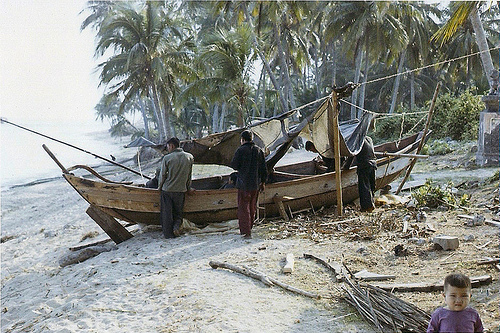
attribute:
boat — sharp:
[46, 122, 497, 224]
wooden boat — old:
[18, 105, 429, 229]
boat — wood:
[47, 77, 447, 244]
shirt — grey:
[149, 146, 196, 195]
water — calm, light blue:
[23, 122, 110, 167]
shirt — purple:
[432, 308, 477, 331]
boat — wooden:
[33, 136, 480, 236]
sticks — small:
[332, 275, 437, 331]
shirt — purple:
[425, 307, 484, 330]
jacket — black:
[227, 140, 269, 191]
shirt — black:
[225, 140, 272, 190]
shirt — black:
[234, 139, 270, 204]